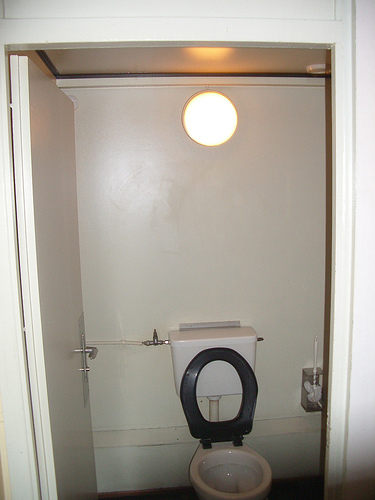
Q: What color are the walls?
A: White.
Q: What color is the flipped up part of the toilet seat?
A: Black.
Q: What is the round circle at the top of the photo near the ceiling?
A: Light.